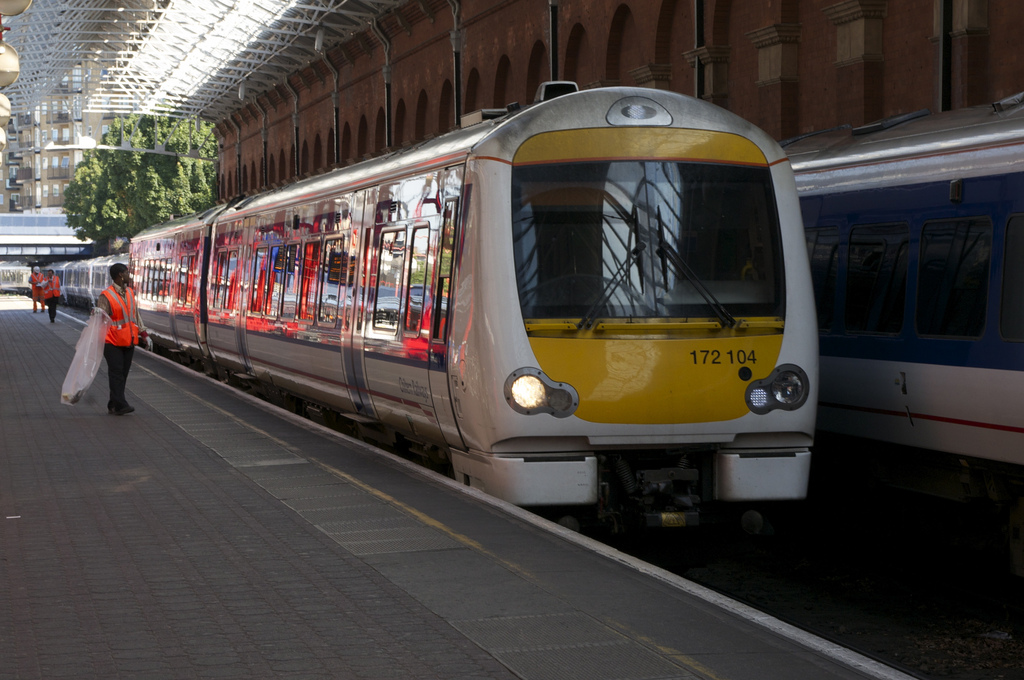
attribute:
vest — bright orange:
[91, 287, 143, 346]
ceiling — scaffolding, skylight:
[13, 8, 314, 127]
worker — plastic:
[98, 253, 148, 418]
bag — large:
[51, 300, 114, 415]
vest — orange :
[103, 277, 145, 368]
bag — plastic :
[51, 309, 103, 383]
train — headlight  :
[129, 57, 916, 559]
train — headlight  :
[505, 327, 819, 442]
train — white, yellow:
[17, 103, 836, 531]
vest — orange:
[91, 289, 143, 352]